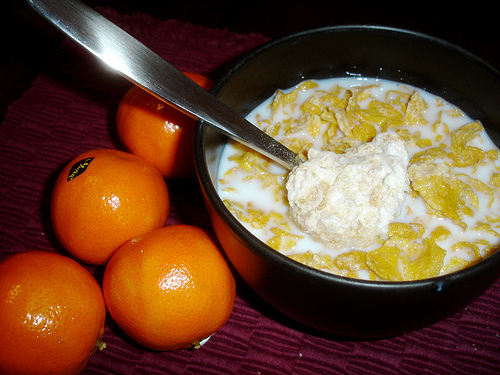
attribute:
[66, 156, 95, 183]
sticker — black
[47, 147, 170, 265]
fruit — unpeeled, bright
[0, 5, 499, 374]
mat — purple, embroidered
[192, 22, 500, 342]
bowl — black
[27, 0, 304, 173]
spoon — silver, large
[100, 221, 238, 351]
orange — unpeeled, bright